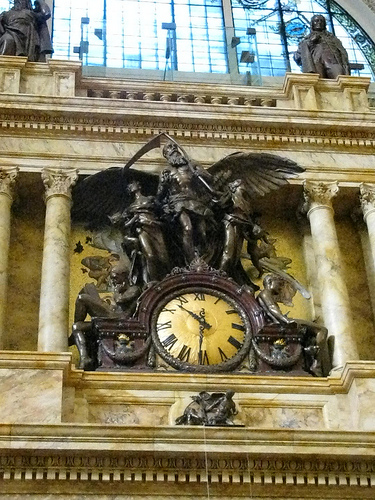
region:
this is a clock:
[149, 272, 259, 372]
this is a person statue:
[296, 8, 351, 80]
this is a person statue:
[59, 253, 154, 374]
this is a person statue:
[242, 231, 305, 321]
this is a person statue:
[122, 176, 179, 284]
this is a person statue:
[154, 137, 231, 269]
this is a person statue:
[226, 167, 280, 265]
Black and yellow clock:
[150, 281, 259, 369]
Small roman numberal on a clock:
[187, 291, 208, 304]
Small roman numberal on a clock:
[208, 288, 229, 309]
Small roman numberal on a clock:
[220, 304, 240, 318]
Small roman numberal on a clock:
[231, 318, 247, 336]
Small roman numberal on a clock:
[224, 331, 243, 357]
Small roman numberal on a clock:
[216, 339, 228, 363]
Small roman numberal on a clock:
[190, 344, 209, 368]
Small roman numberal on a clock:
[177, 340, 198, 371]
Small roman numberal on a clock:
[156, 332, 180, 355]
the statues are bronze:
[93, 142, 244, 273]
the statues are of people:
[96, 135, 248, 240]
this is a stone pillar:
[25, 164, 91, 348]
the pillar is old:
[22, 157, 65, 250]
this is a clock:
[121, 255, 295, 394]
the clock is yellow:
[141, 283, 265, 374]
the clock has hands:
[130, 287, 273, 365]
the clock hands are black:
[137, 275, 250, 368]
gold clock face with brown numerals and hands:
[150, 286, 254, 374]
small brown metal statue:
[173, 388, 245, 430]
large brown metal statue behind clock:
[69, 125, 328, 379]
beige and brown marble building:
[0, 52, 374, 498]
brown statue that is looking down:
[289, 13, 351, 77]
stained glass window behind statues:
[0, 0, 374, 79]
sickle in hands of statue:
[122, 129, 222, 196]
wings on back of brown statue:
[69, 150, 305, 232]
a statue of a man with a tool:
[145, 114, 218, 276]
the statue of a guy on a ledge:
[295, 13, 351, 93]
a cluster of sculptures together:
[102, 149, 291, 277]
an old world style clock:
[140, 285, 260, 370]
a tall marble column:
[38, 157, 81, 361]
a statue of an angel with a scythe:
[78, 134, 312, 240]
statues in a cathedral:
[6, 2, 373, 120]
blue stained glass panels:
[55, 3, 278, 70]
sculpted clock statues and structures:
[5, 96, 369, 393]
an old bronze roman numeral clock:
[75, 277, 341, 372]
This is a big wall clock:
[59, 125, 336, 395]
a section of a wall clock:
[193, 281, 278, 383]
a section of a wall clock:
[136, 292, 207, 373]